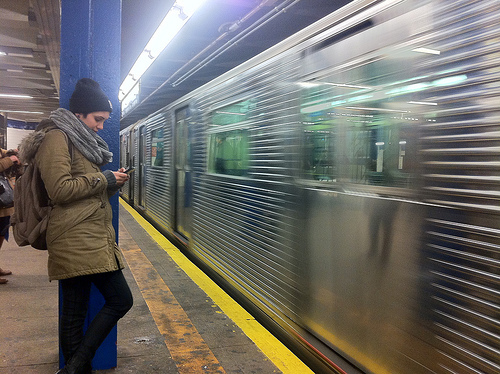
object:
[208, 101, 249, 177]
window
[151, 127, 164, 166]
window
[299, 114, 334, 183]
window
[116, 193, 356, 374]
curb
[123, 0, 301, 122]
pipes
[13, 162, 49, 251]
backpack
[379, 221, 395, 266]
leg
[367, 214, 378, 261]
leg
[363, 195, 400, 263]
passenger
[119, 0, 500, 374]
train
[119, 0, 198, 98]
flourescent lighting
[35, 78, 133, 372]
girl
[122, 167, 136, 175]
phone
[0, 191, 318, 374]
platform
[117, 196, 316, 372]
caution line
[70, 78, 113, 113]
black hat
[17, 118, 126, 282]
coat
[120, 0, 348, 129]
ceiling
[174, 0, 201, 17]
lights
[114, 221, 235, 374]
yellow line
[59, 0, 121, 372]
beam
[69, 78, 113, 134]
head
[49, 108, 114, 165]
scarf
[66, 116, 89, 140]
neck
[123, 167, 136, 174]
cell phone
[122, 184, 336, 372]
tracks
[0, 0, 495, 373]
station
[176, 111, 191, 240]
door